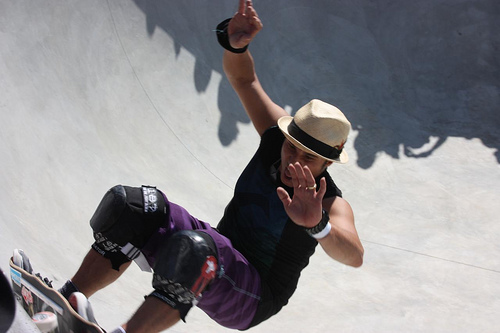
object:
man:
[10, 2, 363, 331]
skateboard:
[8, 256, 108, 332]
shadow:
[192, 59, 213, 95]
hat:
[278, 98, 350, 164]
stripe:
[289, 118, 343, 158]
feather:
[333, 141, 347, 163]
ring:
[306, 184, 317, 190]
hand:
[276, 162, 327, 229]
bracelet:
[313, 222, 333, 239]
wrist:
[312, 213, 337, 246]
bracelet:
[301, 211, 329, 233]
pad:
[153, 230, 206, 296]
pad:
[91, 185, 171, 245]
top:
[216, 126, 341, 305]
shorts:
[137, 201, 263, 329]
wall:
[0, 1, 498, 332]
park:
[0, 2, 498, 333]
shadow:
[134, 0, 499, 168]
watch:
[217, 17, 247, 53]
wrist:
[220, 33, 253, 58]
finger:
[303, 164, 316, 192]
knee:
[157, 230, 216, 300]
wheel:
[33, 311, 58, 332]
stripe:
[218, 265, 262, 301]